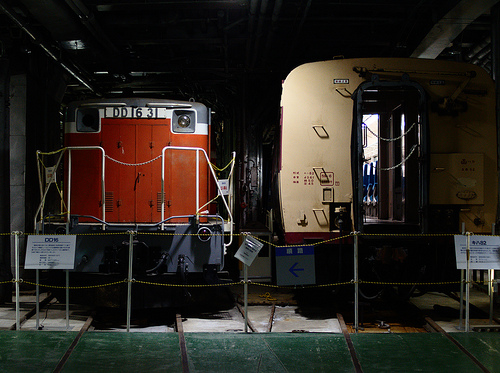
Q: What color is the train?
A: Red.